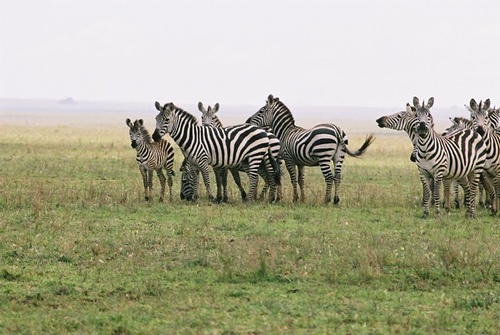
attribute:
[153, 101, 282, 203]
zebra — large, black, white, fully grown, adult, broadside to camera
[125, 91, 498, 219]
zebras — in group, white, black, eight, hidden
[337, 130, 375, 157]
tail — furry, swishing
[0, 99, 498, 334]
on grass — green, grassy, short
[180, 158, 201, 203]
zebra — grazing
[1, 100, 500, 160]
grass — in the distance, yellow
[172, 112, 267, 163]
stripes — black, white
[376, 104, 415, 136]
zebra — braying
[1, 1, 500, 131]
air — distant, hazy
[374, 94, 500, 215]
zebras — in group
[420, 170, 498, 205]
legs — hidden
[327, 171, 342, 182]
back — grey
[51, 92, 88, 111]
something — ufo-shaped, on horizon, a hill, a house, an earth mound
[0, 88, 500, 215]
sky+ground — gradated colors, lavender, yellow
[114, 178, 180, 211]
grass — next to calf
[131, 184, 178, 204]
weeds — long, next to calf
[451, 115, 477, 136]
zebra — hidden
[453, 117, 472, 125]
mane — brushy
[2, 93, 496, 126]
hills — in the background, small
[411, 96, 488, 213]
zebra — medium sized, adult, looking left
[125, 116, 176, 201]
zebra — small, black, white, baby, young, smallest, in group, colt, calf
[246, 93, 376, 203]
zebra — in the middle